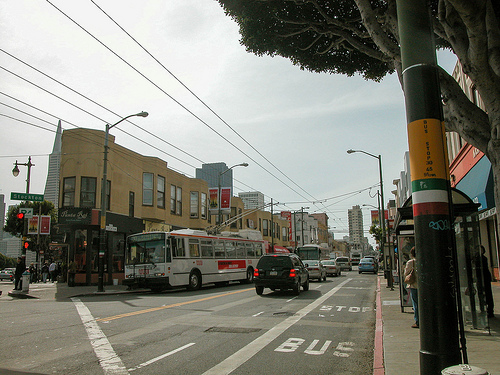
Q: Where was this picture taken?
A: At a bus stop.